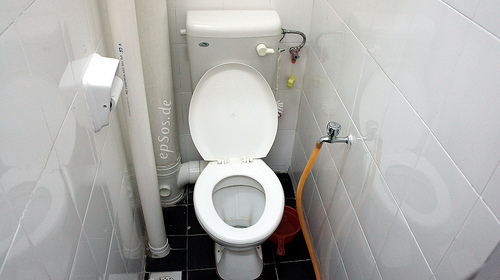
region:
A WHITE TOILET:
[180, 11, 292, 275]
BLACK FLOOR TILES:
[166, 206, 215, 278]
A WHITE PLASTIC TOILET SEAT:
[186, 55, 301, 248]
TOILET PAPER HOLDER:
[77, 43, 127, 133]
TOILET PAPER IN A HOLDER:
[58, 56, 148, 138]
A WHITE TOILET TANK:
[181, 5, 295, 65]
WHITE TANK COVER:
[174, 4, 294, 46]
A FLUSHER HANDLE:
[255, 38, 279, 63]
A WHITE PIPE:
[119, 31, 173, 261]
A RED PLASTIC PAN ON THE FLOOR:
[272, 196, 312, 262]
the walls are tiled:
[362, 79, 474, 165]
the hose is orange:
[294, 155, 330, 235]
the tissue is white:
[109, 81, 131, 106]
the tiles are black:
[177, 242, 204, 273]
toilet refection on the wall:
[362, 130, 453, 235]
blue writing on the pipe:
[113, 47, 141, 124]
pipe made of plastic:
[133, 127, 192, 242]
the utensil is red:
[275, 200, 303, 261]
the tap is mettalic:
[322, 130, 364, 160]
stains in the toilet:
[238, 207, 257, 222]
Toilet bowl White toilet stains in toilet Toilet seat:
[186, 149, 290, 251]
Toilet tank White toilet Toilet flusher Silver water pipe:
[166, 1, 307, 73]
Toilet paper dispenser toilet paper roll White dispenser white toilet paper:
[60, 43, 138, 138]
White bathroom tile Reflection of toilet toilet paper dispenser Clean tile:
[0, 95, 132, 273]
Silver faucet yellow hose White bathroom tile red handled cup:
[265, 108, 372, 278]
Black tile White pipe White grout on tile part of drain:
[122, 196, 209, 276]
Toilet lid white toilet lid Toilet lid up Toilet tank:
[182, 61, 282, 168]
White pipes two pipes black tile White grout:
[126, 118, 224, 268]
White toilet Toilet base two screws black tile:
[195, 211, 279, 276]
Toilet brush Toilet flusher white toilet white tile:
[245, 31, 316, 121]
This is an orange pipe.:
[277, 122, 347, 279]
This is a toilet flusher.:
[249, 37, 278, 60]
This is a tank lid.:
[177, 5, 293, 47]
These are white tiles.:
[391, 22, 498, 134]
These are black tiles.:
[158, 192, 218, 267]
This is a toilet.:
[168, 7, 316, 279]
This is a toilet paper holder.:
[76, 57, 128, 129]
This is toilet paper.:
[103, 69, 125, 117]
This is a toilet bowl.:
[219, 181, 255, 228]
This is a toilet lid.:
[193, 55, 279, 160]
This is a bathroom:
[11, 8, 444, 255]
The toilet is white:
[183, 7, 293, 266]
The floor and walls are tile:
[171, 56, 397, 277]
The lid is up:
[192, 46, 283, 241]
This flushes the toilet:
[250, 21, 278, 70]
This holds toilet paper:
[76, 48, 163, 170]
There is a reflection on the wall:
[13, 66, 140, 268]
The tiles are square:
[347, 34, 476, 180]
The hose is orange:
[299, 112, 346, 273]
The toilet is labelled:
[183, 29, 234, 62]